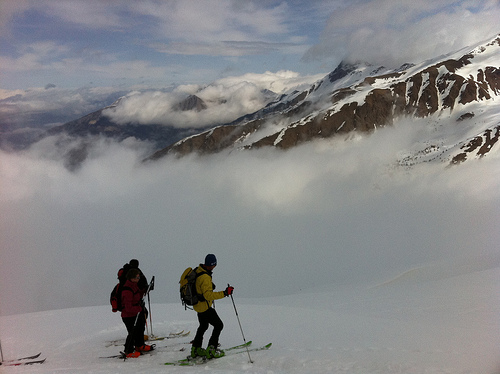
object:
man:
[178, 252, 233, 357]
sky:
[254, 0, 500, 68]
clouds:
[0, 0, 45, 65]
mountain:
[373, 114, 499, 196]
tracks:
[281, 341, 371, 371]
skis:
[103, 327, 185, 343]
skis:
[103, 330, 192, 348]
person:
[108, 257, 155, 359]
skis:
[158, 340, 251, 366]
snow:
[0, 303, 498, 373]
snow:
[406, 141, 485, 183]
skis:
[149, 346, 185, 359]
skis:
[95, 339, 195, 363]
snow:
[19, 225, 445, 299]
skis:
[188, 342, 273, 368]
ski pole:
[224, 282, 253, 364]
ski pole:
[146, 291, 154, 336]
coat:
[172, 264, 224, 313]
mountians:
[168, 91, 211, 115]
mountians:
[21, 91, 139, 173]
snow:
[215, 74, 385, 144]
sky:
[59, 6, 185, 58]